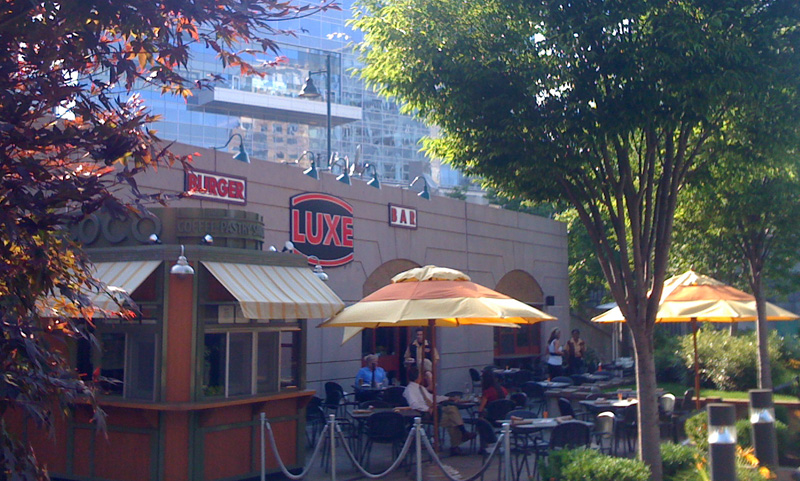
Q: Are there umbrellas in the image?
A: Yes, there is an umbrella.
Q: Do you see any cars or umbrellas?
A: Yes, there is an umbrella.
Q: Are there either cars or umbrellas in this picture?
A: Yes, there is an umbrella.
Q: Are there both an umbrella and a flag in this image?
A: No, there is an umbrella but no flags.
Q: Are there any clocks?
A: No, there are no clocks.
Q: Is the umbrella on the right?
A: Yes, the umbrella is on the right of the image.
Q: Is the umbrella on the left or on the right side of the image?
A: The umbrella is on the right of the image.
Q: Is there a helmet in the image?
A: No, there are no helmets.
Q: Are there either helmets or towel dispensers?
A: No, there are no helmets or towel dispensers.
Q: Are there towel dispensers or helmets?
A: No, there are no helmets or towel dispensers.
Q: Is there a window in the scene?
A: Yes, there is a window.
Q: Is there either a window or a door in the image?
A: Yes, there is a window.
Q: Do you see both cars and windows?
A: No, there is a window but no cars.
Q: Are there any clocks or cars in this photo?
A: No, there are no cars or clocks.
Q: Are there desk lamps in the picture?
A: No, there are no desk lamps.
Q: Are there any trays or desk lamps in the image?
A: No, there are no desk lamps or trays.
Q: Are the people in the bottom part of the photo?
A: Yes, the people are in the bottom of the image.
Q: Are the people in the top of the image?
A: No, the people are in the bottom of the image.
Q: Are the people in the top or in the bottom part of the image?
A: The people are in the bottom of the image.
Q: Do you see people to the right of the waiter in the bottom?
A: Yes, there are people to the right of the waiter.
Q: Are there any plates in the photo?
A: No, there are no plates.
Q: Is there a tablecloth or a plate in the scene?
A: No, there are no plates or tablecloths.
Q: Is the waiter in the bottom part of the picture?
A: Yes, the waiter is in the bottom of the image.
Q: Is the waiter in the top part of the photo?
A: No, the waiter is in the bottom of the image.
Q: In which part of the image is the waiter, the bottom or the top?
A: The waiter is in the bottom of the image.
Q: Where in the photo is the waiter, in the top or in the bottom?
A: The waiter is in the bottom of the image.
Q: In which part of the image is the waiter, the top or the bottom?
A: The waiter is in the bottom of the image.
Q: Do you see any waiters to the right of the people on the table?
A: Yes, there is a waiter to the right of the people.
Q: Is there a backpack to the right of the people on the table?
A: No, there is a waiter to the right of the people.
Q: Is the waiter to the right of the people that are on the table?
A: Yes, the waiter is to the right of the people.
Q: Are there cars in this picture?
A: No, there are no cars.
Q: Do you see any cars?
A: No, there are no cars.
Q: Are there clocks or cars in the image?
A: No, there are no cars or clocks.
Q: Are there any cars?
A: No, there are no cars.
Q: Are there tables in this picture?
A: Yes, there is a table.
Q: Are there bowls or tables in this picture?
A: Yes, there is a table.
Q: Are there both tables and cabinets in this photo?
A: No, there is a table but no cabinets.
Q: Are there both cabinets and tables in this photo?
A: No, there is a table but no cabinets.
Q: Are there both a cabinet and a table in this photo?
A: No, there is a table but no cabinets.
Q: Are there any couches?
A: No, there are no couches.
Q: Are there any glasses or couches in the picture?
A: No, there are no couches or glasses.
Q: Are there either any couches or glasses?
A: No, there are no couches or glasses.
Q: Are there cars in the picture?
A: No, there are no cars.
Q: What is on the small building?
A: The sign is on the building.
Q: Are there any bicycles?
A: No, there are no bicycles.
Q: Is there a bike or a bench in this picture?
A: No, there are no bikes or benches.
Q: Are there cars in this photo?
A: No, there are no cars.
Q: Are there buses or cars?
A: No, there are no cars or buses.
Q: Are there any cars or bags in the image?
A: No, there are no cars or bags.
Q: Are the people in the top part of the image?
A: No, the people are in the bottom of the image.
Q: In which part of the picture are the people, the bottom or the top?
A: The people are in the bottom of the image.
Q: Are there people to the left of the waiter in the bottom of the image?
A: Yes, there are people to the left of the waiter.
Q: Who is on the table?
A: The people are on the table.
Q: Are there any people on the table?
A: Yes, there are people on the table.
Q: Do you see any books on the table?
A: No, there are people on the table.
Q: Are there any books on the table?
A: No, there are people on the table.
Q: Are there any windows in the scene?
A: Yes, there is a window.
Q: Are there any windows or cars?
A: Yes, there is a window.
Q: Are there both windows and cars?
A: No, there is a window but no cars.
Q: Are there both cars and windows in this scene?
A: No, there is a window but no cars.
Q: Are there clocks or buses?
A: No, there are no buses or clocks.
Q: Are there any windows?
A: Yes, there is a window.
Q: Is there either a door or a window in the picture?
A: Yes, there is a window.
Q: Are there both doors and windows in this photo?
A: No, there is a window but no doors.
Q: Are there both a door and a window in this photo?
A: No, there is a window but no doors.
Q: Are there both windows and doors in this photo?
A: No, there is a window but no doors.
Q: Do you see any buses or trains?
A: No, there are no buses or trains.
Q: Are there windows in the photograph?
A: Yes, there is a window.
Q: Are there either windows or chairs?
A: Yes, there is a window.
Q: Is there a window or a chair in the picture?
A: Yes, there is a window.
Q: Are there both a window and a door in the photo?
A: No, there is a window but no doors.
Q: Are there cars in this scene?
A: No, there are no cars.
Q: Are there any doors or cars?
A: No, there are no cars or doors.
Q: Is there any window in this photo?
A: Yes, there is a window.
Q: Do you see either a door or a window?
A: Yes, there is a window.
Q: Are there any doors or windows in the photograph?
A: Yes, there is a window.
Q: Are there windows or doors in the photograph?
A: Yes, there is a window.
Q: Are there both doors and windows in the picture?
A: No, there is a window but no doors.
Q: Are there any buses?
A: No, there are no buses.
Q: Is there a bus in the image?
A: No, there are no buses.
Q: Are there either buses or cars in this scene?
A: No, there are no buses or cars.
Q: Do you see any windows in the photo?
A: Yes, there is a window.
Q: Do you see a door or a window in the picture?
A: Yes, there is a window.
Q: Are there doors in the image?
A: No, there are no doors.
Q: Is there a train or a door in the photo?
A: No, there are no doors or trains.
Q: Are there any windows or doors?
A: Yes, there is a window.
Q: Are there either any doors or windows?
A: Yes, there is a window.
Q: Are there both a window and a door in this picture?
A: No, there is a window but no doors.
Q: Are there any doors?
A: No, there are no doors.